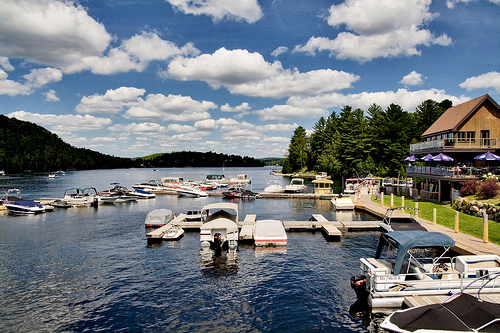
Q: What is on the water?
A: Boats.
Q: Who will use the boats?
A: People.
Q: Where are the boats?
A: In the water.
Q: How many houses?
A: 1.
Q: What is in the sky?
A: Clouds.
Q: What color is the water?
A: Blue.